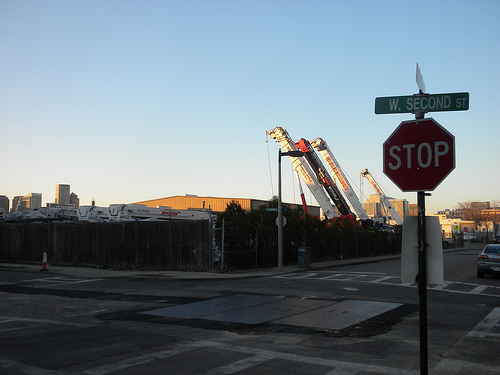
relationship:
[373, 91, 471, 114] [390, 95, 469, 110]
sign reading w. second st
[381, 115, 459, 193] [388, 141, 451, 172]
sign has lettering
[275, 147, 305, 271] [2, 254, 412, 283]
streetlight on sidewalk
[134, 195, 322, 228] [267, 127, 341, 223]
building behind cranes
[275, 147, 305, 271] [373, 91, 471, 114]
streetlight and sign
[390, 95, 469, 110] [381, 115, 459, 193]
w. second st on top of sign